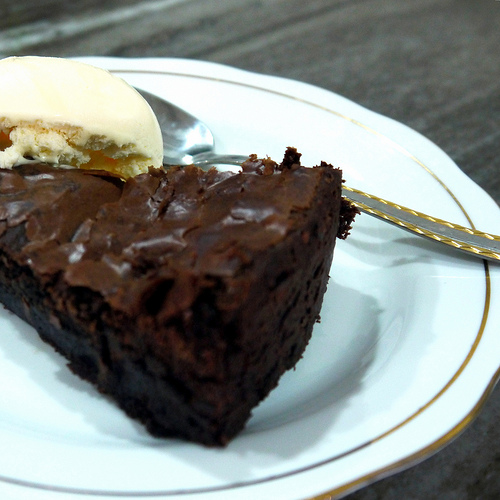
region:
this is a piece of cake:
[2, 138, 369, 452]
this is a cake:
[3, 162, 375, 447]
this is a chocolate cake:
[0, 160, 367, 470]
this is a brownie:
[9, 148, 366, 472]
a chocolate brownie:
[6, 164, 388, 482]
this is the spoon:
[151, 81, 498, 291]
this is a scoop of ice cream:
[0, 51, 180, 188]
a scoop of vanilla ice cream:
[0, 45, 177, 192]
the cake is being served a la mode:
[1, 43, 367, 460]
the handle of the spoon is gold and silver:
[317, 157, 496, 281]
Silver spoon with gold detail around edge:
[134, 82, 498, 263]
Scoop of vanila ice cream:
[1, 52, 164, 177]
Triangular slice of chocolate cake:
[1, 150, 357, 447]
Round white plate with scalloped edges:
[1, 52, 498, 499]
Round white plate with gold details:
[1, 54, 496, 497]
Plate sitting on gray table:
[5, 4, 498, 496]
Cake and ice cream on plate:
[1, 52, 497, 497]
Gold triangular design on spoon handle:
[132, 82, 497, 264]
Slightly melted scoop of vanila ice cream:
[1, 54, 161, 176]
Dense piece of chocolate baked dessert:
[6, 157, 346, 448]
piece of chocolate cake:
[19, 155, 356, 440]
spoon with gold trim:
[131, 89, 488, 260]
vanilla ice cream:
[4, 90, 155, 201]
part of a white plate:
[175, 83, 491, 241]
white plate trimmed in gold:
[297, 390, 455, 489]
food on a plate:
[2, 90, 384, 402]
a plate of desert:
[6, 86, 397, 438]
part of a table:
[405, 100, 496, 156]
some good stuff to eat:
[13, 90, 366, 414]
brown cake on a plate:
[2, 150, 390, 435]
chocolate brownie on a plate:
[2, 150, 374, 462]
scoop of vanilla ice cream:
[0, 40, 166, 183]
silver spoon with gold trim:
[99, 62, 498, 278]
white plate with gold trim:
[0, 50, 499, 496]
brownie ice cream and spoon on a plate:
[3, 40, 498, 497]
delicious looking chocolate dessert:
[0, 30, 495, 496]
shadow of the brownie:
[237, 274, 392, 471]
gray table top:
[13, 0, 498, 199]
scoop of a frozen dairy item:
[1, 49, 168, 180]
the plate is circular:
[3, 41, 498, 494]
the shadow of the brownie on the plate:
[229, 290, 377, 460]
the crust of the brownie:
[0, 151, 311, 295]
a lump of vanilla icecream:
[0, 57, 169, 176]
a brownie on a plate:
[7, 166, 339, 453]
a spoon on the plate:
[113, 82, 495, 259]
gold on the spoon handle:
[329, 178, 498, 257]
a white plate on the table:
[0, 52, 496, 495]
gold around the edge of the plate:
[318, 372, 497, 498]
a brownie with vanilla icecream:
[0, 47, 340, 421]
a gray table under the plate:
[0, 0, 499, 498]